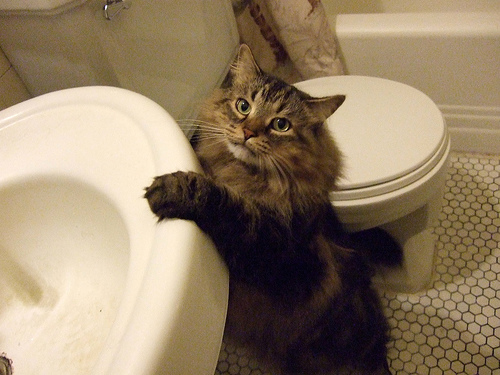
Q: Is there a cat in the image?
A: Yes, there is a cat.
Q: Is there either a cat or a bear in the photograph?
A: Yes, there is a cat.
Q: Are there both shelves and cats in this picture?
A: No, there is a cat but no shelves.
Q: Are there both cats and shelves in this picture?
A: No, there is a cat but no shelves.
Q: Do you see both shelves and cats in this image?
A: No, there is a cat but no shelves.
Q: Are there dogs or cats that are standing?
A: Yes, the cat is standing.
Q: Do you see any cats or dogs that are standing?
A: Yes, the cat is standing.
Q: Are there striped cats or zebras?
A: Yes, there is a striped cat.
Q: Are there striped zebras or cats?
A: Yes, there is a striped cat.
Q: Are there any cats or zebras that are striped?
A: Yes, the cat is striped.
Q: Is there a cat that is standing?
A: Yes, there is a cat that is standing.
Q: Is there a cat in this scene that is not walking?
A: Yes, there is a cat that is standing.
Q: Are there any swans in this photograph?
A: No, there are no swans.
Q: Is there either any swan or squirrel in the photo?
A: No, there are no swans or squirrels.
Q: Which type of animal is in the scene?
A: The animal is a cat.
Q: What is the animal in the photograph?
A: The animal is a cat.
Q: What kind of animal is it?
A: The animal is a cat.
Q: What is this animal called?
A: This is a cat.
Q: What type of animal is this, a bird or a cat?
A: This is a cat.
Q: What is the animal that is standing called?
A: The animal is a cat.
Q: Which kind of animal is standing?
A: The animal is a cat.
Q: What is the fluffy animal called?
A: The animal is a cat.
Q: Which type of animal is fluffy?
A: The animal is a cat.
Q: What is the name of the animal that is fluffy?
A: The animal is a cat.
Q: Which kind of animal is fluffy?
A: The animal is a cat.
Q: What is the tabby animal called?
A: The animal is a cat.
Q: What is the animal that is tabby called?
A: The animal is a cat.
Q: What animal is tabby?
A: The animal is a cat.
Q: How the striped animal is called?
A: The animal is a cat.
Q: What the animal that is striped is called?
A: The animal is a cat.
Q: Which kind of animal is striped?
A: The animal is a cat.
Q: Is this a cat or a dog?
A: This is a cat.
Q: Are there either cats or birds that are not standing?
A: No, there is a cat but it is standing.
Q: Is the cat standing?
A: Yes, the cat is standing.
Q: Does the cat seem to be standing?
A: Yes, the cat is standing.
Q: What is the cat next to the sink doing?
A: The cat is standing.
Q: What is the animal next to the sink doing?
A: The cat is standing.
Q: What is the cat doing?
A: The cat is standing.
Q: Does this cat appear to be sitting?
A: No, the cat is standing.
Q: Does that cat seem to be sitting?
A: No, the cat is standing.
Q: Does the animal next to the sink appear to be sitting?
A: No, the cat is standing.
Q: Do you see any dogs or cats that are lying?
A: No, there is a cat but it is standing.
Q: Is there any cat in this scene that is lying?
A: No, there is a cat but it is standing.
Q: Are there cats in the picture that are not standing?
A: No, there is a cat but it is standing.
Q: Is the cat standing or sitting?
A: The cat is standing.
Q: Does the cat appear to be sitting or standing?
A: The cat is standing.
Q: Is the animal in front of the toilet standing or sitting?
A: The cat is standing.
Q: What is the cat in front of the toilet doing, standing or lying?
A: The cat is standing.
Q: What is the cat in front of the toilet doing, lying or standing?
A: The cat is standing.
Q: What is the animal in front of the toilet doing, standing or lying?
A: The cat is standing.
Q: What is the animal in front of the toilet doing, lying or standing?
A: The cat is standing.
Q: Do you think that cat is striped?
A: Yes, the cat is striped.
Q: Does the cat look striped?
A: Yes, the cat is striped.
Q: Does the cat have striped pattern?
A: Yes, the cat is striped.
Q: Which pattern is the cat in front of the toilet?
A: The cat is striped.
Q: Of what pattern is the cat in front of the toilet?
A: The cat is striped.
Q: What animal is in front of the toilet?
A: The cat is in front of the toilet.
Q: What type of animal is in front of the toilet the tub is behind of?
A: The animal is a cat.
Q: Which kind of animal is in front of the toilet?
A: The animal is a cat.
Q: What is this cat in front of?
A: The cat is in front of the toilet.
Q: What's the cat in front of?
A: The cat is in front of the toilet.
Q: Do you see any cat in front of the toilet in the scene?
A: Yes, there is a cat in front of the toilet.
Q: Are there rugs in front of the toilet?
A: No, there is a cat in front of the toilet.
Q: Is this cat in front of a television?
A: No, the cat is in front of the toilet.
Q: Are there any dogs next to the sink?
A: No, there is a cat next to the sink.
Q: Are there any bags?
A: No, there are no bags.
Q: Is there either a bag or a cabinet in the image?
A: No, there are no bags or cabinets.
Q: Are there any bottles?
A: No, there are no bottles.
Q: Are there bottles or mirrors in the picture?
A: No, there are no bottles or mirrors.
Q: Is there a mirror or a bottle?
A: No, there are no bottles or mirrors.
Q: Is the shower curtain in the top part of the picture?
A: Yes, the shower curtain is in the top of the image.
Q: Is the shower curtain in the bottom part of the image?
A: No, the shower curtain is in the top of the image.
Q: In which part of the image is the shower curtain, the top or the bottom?
A: The shower curtain is in the top of the image.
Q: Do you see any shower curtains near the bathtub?
A: Yes, there is a shower curtain near the bathtub.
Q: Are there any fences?
A: No, there are no fences.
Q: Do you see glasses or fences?
A: No, there are no fences or glasses.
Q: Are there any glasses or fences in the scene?
A: No, there are no fences or glasses.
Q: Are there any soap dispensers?
A: No, there are no soap dispensers.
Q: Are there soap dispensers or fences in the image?
A: No, there are no soap dispensers or fences.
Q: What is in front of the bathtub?
A: The toilet is in front of the bathtub.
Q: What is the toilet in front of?
A: The toilet is in front of the tub.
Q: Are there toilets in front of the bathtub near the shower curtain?
A: Yes, there is a toilet in front of the tub.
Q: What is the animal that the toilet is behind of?
A: The animal is a cat.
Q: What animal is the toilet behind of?
A: The toilet is behind the cat.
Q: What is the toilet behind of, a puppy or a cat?
A: The toilet is behind a cat.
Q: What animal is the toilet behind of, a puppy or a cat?
A: The toilet is behind a cat.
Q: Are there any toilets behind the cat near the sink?
A: Yes, there is a toilet behind the cat.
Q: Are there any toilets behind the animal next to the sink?
A: Yes, there is a toilet behind the cat.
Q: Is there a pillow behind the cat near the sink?
A: No, there is a toilet behind the cat.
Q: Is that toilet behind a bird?
A: No, the toilet is behind a cat.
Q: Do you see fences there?
A: No, there are no fences.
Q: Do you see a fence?
A: No, there are no fences.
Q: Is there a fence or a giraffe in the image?
A: No, there are no fences or giraffes.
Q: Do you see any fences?
A: No, there are no fences.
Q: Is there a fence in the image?
A: No, there are no fences.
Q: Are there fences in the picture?
A: No, there are no fences.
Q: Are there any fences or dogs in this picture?
A: No, there are no fences or dogs.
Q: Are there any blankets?
A: No, there are no blankets.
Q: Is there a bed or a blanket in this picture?
A: No, there are no blankets or beds.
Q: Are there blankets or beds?
A: No, there are no blankets or beds.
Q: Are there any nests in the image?
A: No, there are no nests.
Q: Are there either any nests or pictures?
A: No, there are no nests or pictures.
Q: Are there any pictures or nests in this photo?
A: No, there are no nests or pictures.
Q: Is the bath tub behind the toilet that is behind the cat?
A: Yes, the bath tub is behind the toilet.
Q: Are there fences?
A: No, there are no fences.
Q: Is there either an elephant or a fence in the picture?
A: No, there are no fences or elephants.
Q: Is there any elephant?
A: No, there are no elephants.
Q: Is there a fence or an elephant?
A: No, there are no elephants or fences.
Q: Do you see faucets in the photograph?
A: No, there are no faucets.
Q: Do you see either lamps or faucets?
A: No, there are no faucets or lamps.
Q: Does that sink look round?
A: Yes, the sink is round.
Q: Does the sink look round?
A: Yes, the sink is round.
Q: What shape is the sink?
A: The sink is round.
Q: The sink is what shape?
A: The sink is round.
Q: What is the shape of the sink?
A: The sink is round.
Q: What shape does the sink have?
A: The sink has round shape.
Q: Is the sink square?
A: No, the sink is round.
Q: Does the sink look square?
A: No, the sink is round.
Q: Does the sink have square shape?
A: No, the sink is round.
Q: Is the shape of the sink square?
A: No, the sink is round.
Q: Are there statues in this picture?
A: No, there are no statues.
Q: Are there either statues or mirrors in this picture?
A: No, there are no statues or mirrors.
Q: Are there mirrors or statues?
A: No, there are no statues or mirrors.